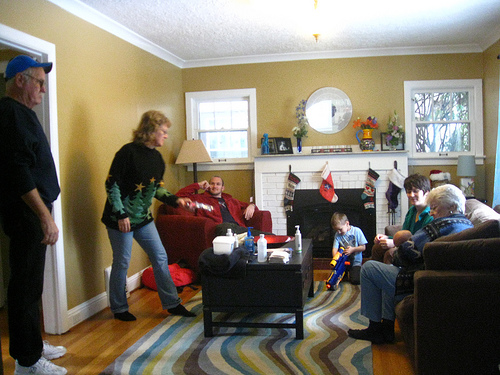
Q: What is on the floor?
A: A rug.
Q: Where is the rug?
A: On the floor.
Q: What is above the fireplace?
A: Stockings.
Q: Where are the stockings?
A: Above the fireplace.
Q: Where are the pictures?
A: On the mantle.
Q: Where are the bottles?
A: On the table.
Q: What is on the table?
A: Bottles.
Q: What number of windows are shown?
A: Two.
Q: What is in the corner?
A: A lamp.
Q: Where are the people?
A: In a living room.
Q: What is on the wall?
A: A picture.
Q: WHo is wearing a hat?
A: The older man.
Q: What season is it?
A: Christmas.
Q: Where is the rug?
A: On the floor.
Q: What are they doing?
A: Talking.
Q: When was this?
A: Daytime.